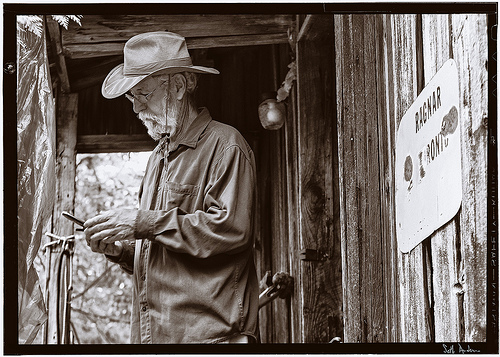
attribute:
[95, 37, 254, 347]
man — old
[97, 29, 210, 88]
hat — cowboy style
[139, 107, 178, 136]
beard — white, short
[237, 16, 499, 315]
building — wood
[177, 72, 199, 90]
hair — white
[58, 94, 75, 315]
beam — wooden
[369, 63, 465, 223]
sign — white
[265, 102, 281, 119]
bulb — white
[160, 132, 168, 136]
knob — black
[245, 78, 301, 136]
lighting — OUTDOOR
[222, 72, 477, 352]
house — OUTDOOR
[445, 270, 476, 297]
fern — POKING